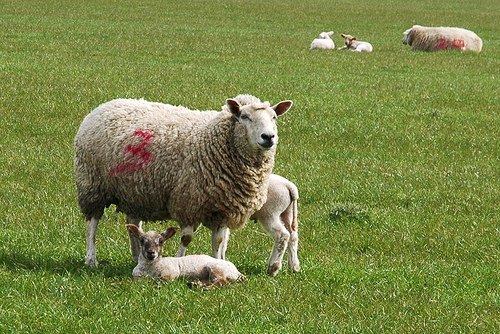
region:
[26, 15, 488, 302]
sheep in a field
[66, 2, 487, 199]
these sheep have been tagged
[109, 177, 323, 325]
these are lambs next to the sheep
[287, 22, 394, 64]
lambs in the grass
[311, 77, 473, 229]
neat clean grass for the sheep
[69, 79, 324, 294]
the sheep and its lamb babies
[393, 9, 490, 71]
this sheep is lying down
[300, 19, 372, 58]
the lambs are lying down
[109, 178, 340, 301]
the lambs are near the sheep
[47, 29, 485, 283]
these sheep are enjoying the grass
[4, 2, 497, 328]
trimmed green grass on ground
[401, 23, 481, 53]
sheep laying in grass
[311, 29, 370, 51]
two lambs on grass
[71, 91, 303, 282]
sheep with two lambs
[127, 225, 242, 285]
lamb reclined on grass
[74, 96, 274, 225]
long coat on sheep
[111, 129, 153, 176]
red number on wool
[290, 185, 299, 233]
tail on back of animal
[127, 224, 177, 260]
lamb looking at camera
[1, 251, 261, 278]
shadow on top of grass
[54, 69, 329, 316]
sheep mom with lambs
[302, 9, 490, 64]
sheep mom with lambs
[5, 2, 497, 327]
sheeps on a green grass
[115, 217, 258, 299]
a lamb lying on the green grass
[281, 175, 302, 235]
a tail color white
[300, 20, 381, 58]
two lambs on the grass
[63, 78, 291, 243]
a sheep with a red mark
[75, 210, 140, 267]
back legs of sheep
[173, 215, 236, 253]
front legs of sheep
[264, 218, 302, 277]
back legs of a lamb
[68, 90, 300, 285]
msms dhrrp with two babies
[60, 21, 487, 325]
lambing time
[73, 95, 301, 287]
ewe with two lambs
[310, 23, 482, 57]
ewe with two lambs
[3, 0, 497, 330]
ewes with lambs in grassy pasture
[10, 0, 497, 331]
wheep standing and lying in a pasture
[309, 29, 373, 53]
two white lambs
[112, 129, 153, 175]
red identification marking on ewe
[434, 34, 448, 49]
red paint identification number 2 on ewe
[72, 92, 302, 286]
mama sheep standing protectively with her two lambs